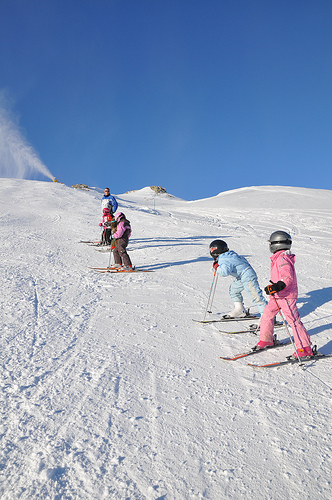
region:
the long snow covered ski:
[249, 349, 330, 368]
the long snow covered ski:
[220, 332, 296, 362]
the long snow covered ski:
[190, 316, 264, 321]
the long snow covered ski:
[219, 325, 258, 335]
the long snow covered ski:
[93, 267, 148, 274]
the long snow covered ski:
[89, 265, 120, 270]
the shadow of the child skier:
[273, 317, 330, 360]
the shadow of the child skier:
[264, 282, 331, 323]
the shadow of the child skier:
[136, 252, 248, 270]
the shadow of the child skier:
[125, 241, 202, 251]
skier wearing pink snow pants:
[253, 230, 315, 360]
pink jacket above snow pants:
[266, 249, 297, 297]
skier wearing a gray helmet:
[268, 227, 293, 251]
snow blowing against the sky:
[0, 130, 55, 181]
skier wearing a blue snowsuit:
[213, 251, 265, 317]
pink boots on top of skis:
[289, 345, 314, 359]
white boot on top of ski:
[228, 302, 246, 316]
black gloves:
[264, 279, 285, 294]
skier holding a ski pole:
[271, 292, 310, 369]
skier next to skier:
[204, 240, 271, 318]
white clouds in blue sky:
[28, 10, 64, 41]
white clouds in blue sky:
[138, 132, 177, 152]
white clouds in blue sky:
[186, 91, 285, 169]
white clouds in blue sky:
[116, 107, 172, 141]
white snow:
[84, 360, 135, 403]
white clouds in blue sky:
[45, 46, 70, 89]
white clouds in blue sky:
[214, 45, 284, 102]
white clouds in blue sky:
[94, 50, 133, 89]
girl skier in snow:
[249, 228, 311, 377]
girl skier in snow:
[172, 214, 256, 335]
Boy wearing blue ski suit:
[191, 239, 267, 322]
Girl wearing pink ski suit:
[218, 230, 329, 368]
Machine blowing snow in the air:
[0, 91, 65, 184]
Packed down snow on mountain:
[4, 189, 330, 497]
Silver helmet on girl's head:
[267, 230, 292, 251]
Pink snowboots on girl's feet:
[256, 337, 314, 358]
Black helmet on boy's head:
[209, 238, 228, 256]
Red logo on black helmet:
[208, 245, 216, 251]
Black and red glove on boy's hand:
[212, 261, 220, 271]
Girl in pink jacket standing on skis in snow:
[89, 212, 155, 275]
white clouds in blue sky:
[32, 14, 88, 75]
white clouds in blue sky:
[149, 53, 190, 100]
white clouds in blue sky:
[196, 67, 264, 102]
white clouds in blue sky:
[96, 126, 155, 165]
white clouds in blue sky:
[56, 41, 103, 80]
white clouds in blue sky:
[127, 49, 184, 89]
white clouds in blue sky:
[185, 27, 239, 101]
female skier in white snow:
[96, 204, 135, 293]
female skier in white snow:
[200, 227, 258, 307]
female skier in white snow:
[246, 227, 327, 385]